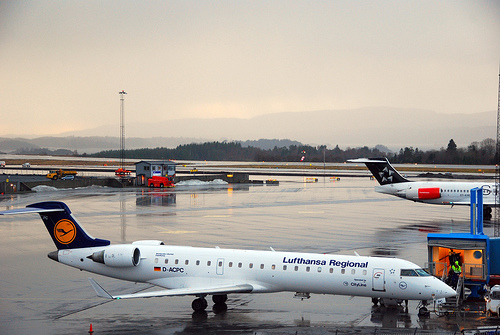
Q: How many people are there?
A: One.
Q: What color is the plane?
A: White.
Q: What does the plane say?
A: Lufthansa Regional.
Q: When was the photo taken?
A: Daytime.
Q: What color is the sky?
A: Gray.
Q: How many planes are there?
A: Two.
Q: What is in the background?
A: Trees.